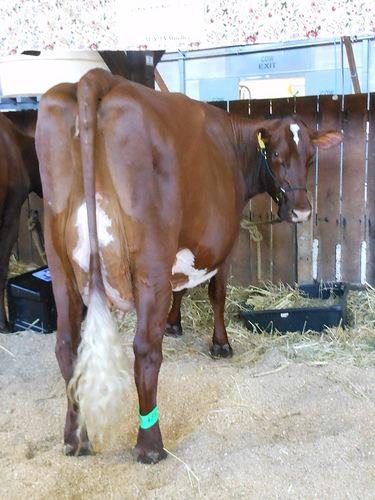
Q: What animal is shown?
A: A cow.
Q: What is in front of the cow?
A: A fence.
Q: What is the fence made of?
A: Wood.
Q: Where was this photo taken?
A: In a barn.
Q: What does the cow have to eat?
A: Hay.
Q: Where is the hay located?
A: On the ground.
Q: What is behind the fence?
A: An exit.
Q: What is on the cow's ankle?
A: A tag.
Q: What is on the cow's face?
A: A harness.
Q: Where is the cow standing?
A: In hay.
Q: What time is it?
A: Afternoon.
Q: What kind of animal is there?
A: Cow.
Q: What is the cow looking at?
A: The camera.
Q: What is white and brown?
A: Cow.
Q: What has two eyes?
A: The cow.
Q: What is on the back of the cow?
A: Tail.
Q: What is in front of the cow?
A: A fence.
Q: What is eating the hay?
A: A cow.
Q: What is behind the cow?
A: A tail.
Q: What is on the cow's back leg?
A: A blue bracelet.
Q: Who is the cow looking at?
A: The person taking the picture.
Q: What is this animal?
A: Cow.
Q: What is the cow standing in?
A: Stall.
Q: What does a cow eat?
A: Hay.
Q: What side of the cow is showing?
A: Rear.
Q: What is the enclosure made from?
A: Wood.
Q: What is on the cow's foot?
A: Tag.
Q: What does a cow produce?
A: Milk.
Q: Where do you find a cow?
A: Farm.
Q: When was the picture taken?
A: Daytime.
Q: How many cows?
A: Two.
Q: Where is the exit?
A: Outside the fence.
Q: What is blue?
A: The exit door.